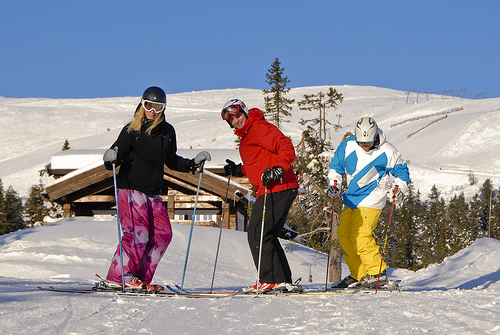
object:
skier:
[326, 117, 408, 289]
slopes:
[390, 106, 477, 144]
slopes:
[349, 85, 443, 114]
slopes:
[22, 96, 94, 131]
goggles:
[221, 104, 240, 120]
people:
[101, 86, 209, 289]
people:
[219, 97, 294, 289]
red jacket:
[220, 98, 298, 199]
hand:
[392, 177, 408, 194]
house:
[33, 163, 248, 231]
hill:
[0, 82, 500, 150]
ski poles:
[325, 180, 336, 292]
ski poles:
[111, 146, 127, 297]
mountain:
[0, 82, 500, 199]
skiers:
[94, 86, 210, 289]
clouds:
[147, 27, 328, 65]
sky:
[3, 0, 500, 37]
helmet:
[221, 99, 249, 128]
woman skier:
[102, 86, 211, 289]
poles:
[253, 186, 267, 298]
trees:
[467, 177, 494, 230]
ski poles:
[177, 161, 199, 294]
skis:
[165, 274, 372, 298]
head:
[354, 116, 378, 149]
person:
[326, 117, 407, 289]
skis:
[35, 286, 241, 299]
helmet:
[142, 86, 166, 103]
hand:
[224, 158, 244, 177]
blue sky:
[1, 0, 498, 98]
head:
[220, 99, 249, 129]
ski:
[165, 285, 345, 298]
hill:
[0, 216, 499, 335]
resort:
[44, 164, 246, 228]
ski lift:
[342, 89, 500, 130]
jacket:
[233, 107, 300, 199]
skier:
[220, 98, 299, 293]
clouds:
[341, 42, 371, 64]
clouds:
[323, 31, 376, 61]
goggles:
[142, 99, 164, 112]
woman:
[102, 86, 211, 290]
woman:
[220, 98, 300, 292]